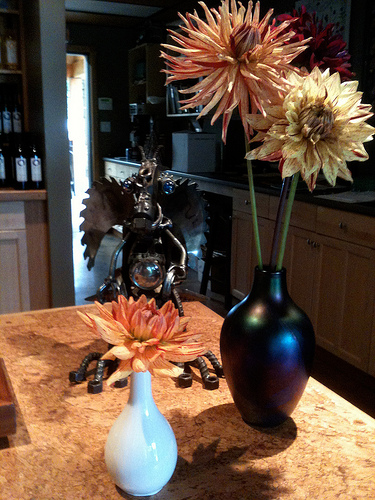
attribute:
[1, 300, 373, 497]
table — marble, brown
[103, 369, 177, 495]
vase — small, white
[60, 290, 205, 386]
flower — reddish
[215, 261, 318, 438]
vase — black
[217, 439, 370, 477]
granite — orange, brown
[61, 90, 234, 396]
decoration — bizarre, iron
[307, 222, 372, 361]
cabinets — wooden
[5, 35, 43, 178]
bottles — wine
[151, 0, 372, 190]
flowers — withering, orange , yellow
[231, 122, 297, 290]
stems — green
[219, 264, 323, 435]
vase — black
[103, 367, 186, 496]
vase — white, small, blue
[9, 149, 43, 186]
bottles — wine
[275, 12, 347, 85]
flower — red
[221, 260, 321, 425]
vase — black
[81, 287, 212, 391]
flower — orange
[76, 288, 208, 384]
flower — orange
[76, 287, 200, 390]
flower — orange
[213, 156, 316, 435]
vase — dark blue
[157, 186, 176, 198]
lights — blue